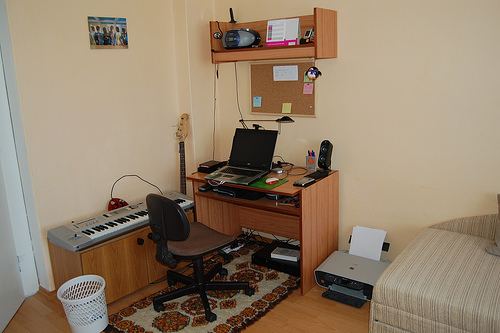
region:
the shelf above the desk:
[211, 17, 345, 65]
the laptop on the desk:
[213, 126, 275, 188]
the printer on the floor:
[316, 233, 383, 310]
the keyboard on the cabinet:
[46, 187, 196, 254]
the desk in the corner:
[186, 152, 342, 293]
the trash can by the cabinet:
[55, 270, 112, 330]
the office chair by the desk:
[147, 195, 249, 322]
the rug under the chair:
[106, 238, 305, 331]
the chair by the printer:
[373, 214, 497, 327]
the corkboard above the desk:
[249, 62, 323, 111]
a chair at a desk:
[148, 191, 245, 313]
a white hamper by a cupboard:
[51, 265, 114, 330]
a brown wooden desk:
[190, 155, 338, 278]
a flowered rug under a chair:
[100, 220, 320, 325]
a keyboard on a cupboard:
[46, 177, 197, 248]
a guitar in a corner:
[171, 118, 192, 194]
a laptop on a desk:
[212, 119, 289, 204]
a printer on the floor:
[306, 218, 405, 315]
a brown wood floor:
[7, 266, 403, 330]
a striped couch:
[370, 214, 496, 327]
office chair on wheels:
[145, 193, 260, 323]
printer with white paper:
[307, 214, 393, 307]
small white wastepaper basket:
[50, 268, 116, 328]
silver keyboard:
[45, 184, 199, 252]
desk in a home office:
[186, 14, 346, 306]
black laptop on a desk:
[194, 119, 291, 196]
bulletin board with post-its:
[246, 56, 328, 121]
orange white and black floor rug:
[115, 241, 300, 331]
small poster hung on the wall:
[67, 1, 146, 67]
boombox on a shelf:
[199, 16, 269, 63]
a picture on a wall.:
[76, 10, 133, 71]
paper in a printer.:
[337, 222, 404, 274]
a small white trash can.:
[50, 260, 125, 330]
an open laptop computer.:
[191, 105, 298, 195]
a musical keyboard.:
[37, 190, 198, 251]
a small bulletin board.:
[238, 57, 342, 135]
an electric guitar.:
[155, 98, 200, 208]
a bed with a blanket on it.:
[363, 165, 498, 332]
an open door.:
[0, 0, 57, 332]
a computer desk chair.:
[147, 189, 264, 322]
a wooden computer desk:
[183, 153, 340, 293]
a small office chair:
[145, 192, 253, 320]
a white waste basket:
[56, 273, 109, 330]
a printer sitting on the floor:
[313, 225, 392, 310]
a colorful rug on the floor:
[103, 232, 300, 331]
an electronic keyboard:
[43, 189, 193, 251]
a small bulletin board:
[247, 59, 318, 119]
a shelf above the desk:
[208, 7, 337, 64]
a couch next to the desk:
[370, 190, 499, 332]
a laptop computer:
[204, 125, 276, 185]